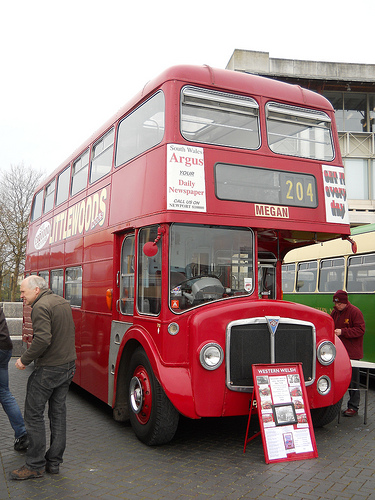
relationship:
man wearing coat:
[329, 290, 365, 419] [330, 305, 365, 357]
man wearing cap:
[329, 290, 365, 419] [333, 289, 346, 303]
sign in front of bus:
[242, 361, 318, 462] [6, 51, 359, 450]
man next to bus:
[13, 276, 100, 466] [130, 65, 331, 393]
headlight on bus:
[195, 327, 235, 389] [19, 57, 353, 475]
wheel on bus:
[125, 363, 178, 448] [84, 235, 210, 424]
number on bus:
[278, 167, 319, 211] [6, 51, 359, 450]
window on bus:
[64, 267, 84, 309] [6, 51, 359, 450]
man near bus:
[9, 274, 77, 480] [6, 51, 359, 450]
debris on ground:
[88, 467, 95, 472] [164, 448, 199, 481]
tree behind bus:
[0, 161, 36, 299] [19, 57, 353, 475]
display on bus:
[214, 158, 323, 211] [11, 70, 356, 436]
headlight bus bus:
[200, 342, 226, 371] [6, 51, 359, 450]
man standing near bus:
[329, 290, 365, 419] [6, 51, 359, 450]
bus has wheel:
[6, 51, 359, 450] [175, 271, 224, 306]